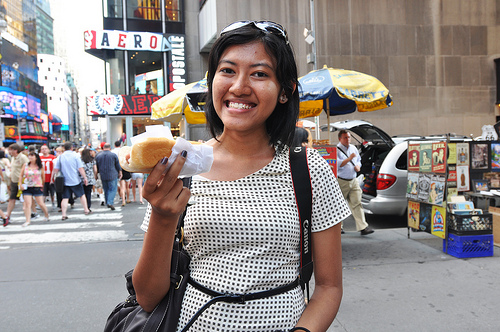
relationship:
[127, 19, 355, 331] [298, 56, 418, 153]
woman has umbrella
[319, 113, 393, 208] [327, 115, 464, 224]
hatchback on car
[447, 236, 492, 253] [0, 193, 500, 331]
carton on road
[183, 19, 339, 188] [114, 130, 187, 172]
woman holding hot dog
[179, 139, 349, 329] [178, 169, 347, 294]
pattern on dress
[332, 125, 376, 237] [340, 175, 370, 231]
man in pants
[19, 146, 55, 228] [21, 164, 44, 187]
woman wearing sleeveless top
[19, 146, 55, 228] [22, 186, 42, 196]
woman wearing shorts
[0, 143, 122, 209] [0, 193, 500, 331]
people crossing road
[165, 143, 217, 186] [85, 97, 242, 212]
paper on hot dog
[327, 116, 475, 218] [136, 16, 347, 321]
car parked behind woman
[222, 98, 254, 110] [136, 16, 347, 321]
teeth on woman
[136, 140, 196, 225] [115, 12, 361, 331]
hand on woman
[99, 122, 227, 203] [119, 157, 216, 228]
hotdog in hand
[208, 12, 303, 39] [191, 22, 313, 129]
sunglasses on head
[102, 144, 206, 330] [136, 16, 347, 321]
purse on woman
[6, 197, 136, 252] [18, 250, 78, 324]
stripes on road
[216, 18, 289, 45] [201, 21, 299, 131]
sunglasses on head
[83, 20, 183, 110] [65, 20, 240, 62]
sign with letters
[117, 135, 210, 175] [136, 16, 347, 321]
hotdog held by woman